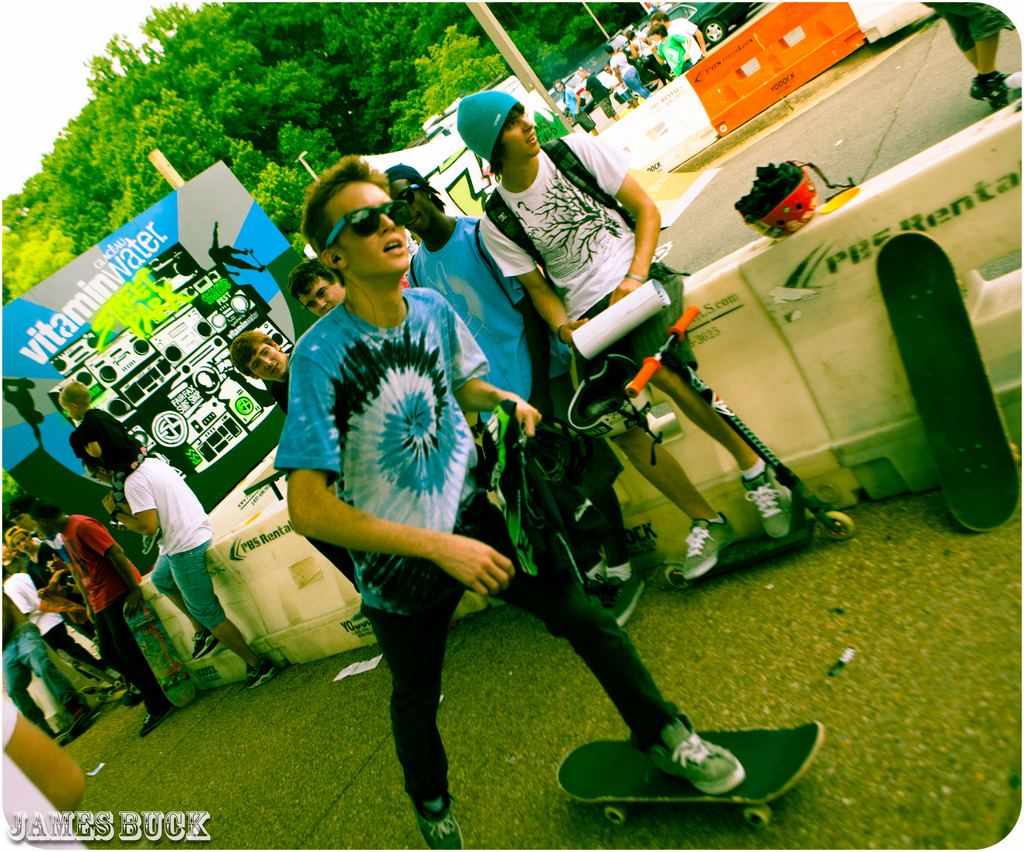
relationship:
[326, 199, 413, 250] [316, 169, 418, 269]
sunglasses on face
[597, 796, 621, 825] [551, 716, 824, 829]
wheel under skateboard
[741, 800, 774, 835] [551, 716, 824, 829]
wheel under skateboard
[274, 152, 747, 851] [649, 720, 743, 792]
boy with foot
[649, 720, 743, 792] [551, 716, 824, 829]
foot on skateboard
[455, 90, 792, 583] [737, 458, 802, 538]
boy with feet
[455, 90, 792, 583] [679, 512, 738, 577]
boy with feet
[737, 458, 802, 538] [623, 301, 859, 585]
feet on scooter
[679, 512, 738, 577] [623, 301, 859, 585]
feet on scooter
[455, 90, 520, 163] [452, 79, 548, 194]
beanie cap on head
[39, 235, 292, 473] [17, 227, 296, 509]
boom boxes on sign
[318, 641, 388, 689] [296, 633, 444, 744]
paper on ground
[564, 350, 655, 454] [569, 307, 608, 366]
helmet in h hand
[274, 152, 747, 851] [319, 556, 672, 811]
boy with feet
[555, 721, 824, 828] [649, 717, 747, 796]
skateboard under foot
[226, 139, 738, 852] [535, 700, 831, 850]
boy riding skateboard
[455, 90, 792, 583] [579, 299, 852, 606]
boy on scooter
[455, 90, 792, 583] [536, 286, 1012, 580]
boy sitting on wall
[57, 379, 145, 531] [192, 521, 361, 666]
child sitting on wall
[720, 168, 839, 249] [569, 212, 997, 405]
helmet on wall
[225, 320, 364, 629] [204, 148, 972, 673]
person sitting on wall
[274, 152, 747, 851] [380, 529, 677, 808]
boy wearing jeans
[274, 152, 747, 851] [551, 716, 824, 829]
boy riding skateboard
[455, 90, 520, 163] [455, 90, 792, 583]
beanie cap on boy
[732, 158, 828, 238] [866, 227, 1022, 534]
helmet above skateboard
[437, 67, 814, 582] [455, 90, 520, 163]
boy wearing beanie cap